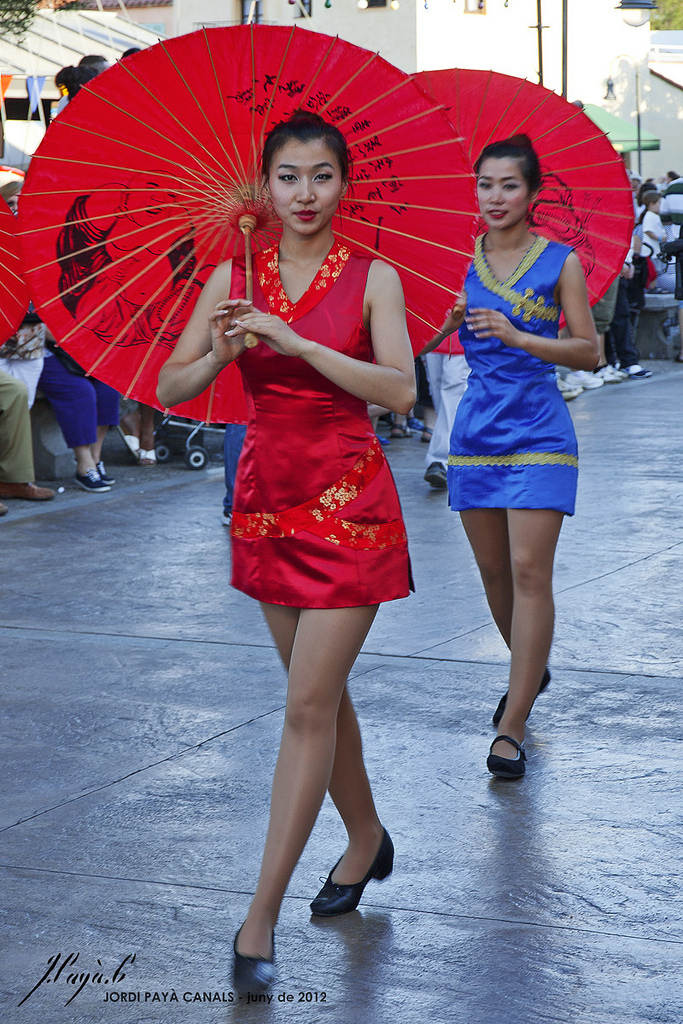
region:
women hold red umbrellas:
[89, 46, 592, 410]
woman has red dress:
[161, 225, 467, 632]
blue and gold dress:
[433, 210, 585, 510]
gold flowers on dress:
[304, 420, 366, 583]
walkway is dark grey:
[1, 674, 100, 855]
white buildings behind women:
[7, 16, 621, 203]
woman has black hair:
[234, 63, 343, 197]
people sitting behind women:
[9, 173, 660, 471]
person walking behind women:
[386, 354, 454, 506]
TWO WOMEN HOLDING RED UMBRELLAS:
[11, 16, 641, 1006]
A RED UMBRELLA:
[11, 17, 487, 433]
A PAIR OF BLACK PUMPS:
[221, 820, 401, 1006]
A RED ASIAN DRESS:
[219, 236, 424, 617]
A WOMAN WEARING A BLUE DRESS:
[440, 127, 608, 787]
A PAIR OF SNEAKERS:
[69, 463, 124, 496]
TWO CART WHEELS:
[150, 430, 215, 474]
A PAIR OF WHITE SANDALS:
[112, 410, 162, 474]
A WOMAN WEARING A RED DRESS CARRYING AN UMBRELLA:
[148, 104, 428, 1001]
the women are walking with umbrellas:
[21, 23, 615, 815]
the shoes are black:
[109, 750, 451, 1012]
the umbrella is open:
[12, 35, 481, 395]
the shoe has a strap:
[451, 712, 549, 793]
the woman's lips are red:
[267, 192, 330, 234]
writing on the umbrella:
[202, 29, 422, 233]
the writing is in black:
[146, 61, 425, 249]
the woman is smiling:
[388, 124, 547, 237]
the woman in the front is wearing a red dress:
[129, 91, 440, 639]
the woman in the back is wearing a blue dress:
[358, 16, 598, 687]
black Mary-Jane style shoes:
[477, 658, 553, 790]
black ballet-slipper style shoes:
[191, 823, 402, 1022]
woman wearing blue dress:
[432, 122, 599, 787]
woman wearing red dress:
[153, 113, 408, 996]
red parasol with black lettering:
[14, 23, 484, 424]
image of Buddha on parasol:
[34, 163, 217, 361]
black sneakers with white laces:
[71, 455, 120, 500]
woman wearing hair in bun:
[150, 105, 411, 1000]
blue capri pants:
[27, 351, 132, 503]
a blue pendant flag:
[24, 64, 47, 121]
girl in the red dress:
[167, 89, 418, 993]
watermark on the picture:
[14, 929, 368, 1022]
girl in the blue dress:
[428, 124, 598, 819]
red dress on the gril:
[224, 230, 431, 636]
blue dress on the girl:
[444, 219, 612, 552]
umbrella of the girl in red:
[16, 19, 481, 455]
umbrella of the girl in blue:
[388, 45, 641, 351]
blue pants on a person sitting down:
[29, 344, 151, 524]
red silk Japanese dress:
[228, 237, 418, 606]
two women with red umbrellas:
[17, 16, 635, 990]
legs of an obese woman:
[41, 366, 120, 489]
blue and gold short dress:
[448, 233, 577, 514]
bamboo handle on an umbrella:
[237, 214, 261, 348]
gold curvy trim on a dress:
[445, 453, 578, 470]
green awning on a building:
[567, 101, 662, 155]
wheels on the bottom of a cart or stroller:
[149, 442, 202, 465]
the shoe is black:
[229, 919, 277, 997]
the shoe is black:
[309, 828, 394, 913]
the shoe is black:
[488, 733, 527, 778]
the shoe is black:
[491, 664, 552, 722]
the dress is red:
[230, 241, 415, 610]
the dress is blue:
[448, 228, 580, 515]